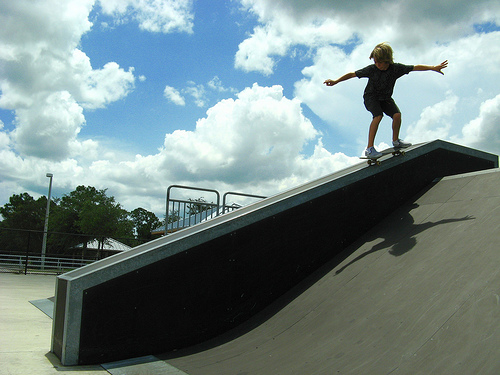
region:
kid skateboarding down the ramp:
[65, 30, 463, 336]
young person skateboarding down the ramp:
[35, 21, 457, 336]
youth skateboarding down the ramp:
[45, 12, 455, 328]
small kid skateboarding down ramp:
[20, 20, 465, 321]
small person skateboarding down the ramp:
[75, 30, 465, 325]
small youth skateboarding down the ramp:
[90, 25, 457, 325]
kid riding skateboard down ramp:
[41, 15, 468, 330]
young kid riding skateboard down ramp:
[57, 21, 459, 316]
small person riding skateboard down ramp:
[65, 20, 462, 295]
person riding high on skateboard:
[301, 8, 457, 206]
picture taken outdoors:
[34, 44, 489, 320]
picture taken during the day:
[44, 30, 461, 358]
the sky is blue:
[76, 37, 174, 131]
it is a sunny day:
[72, 60, 172, 187]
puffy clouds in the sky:
[69, 9, 314, 202]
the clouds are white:
[60, 55, 319, 168]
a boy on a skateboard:
[305, 20, 435, 209]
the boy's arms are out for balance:
[300, 45, 476, 96]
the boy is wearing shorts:
[326, 108, 415, 127]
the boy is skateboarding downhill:
[77, 142, 496, 292]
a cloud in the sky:
[13, 91, 87, 175]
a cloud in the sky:
[99, 59, 138, 102]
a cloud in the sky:
[98, 152, 140, 189]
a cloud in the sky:
[159, 122, 204, 182]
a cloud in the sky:
[1, 148, 28, 184]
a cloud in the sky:
[23, 15, 83, 70]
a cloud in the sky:
[237, 16, 281, 78]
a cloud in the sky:
[309, 59, 344, 130]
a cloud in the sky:
[235, 85, 305, 167]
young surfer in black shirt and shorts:
[325, 42, 448, 166]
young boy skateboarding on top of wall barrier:
[318, 42, 450, 164]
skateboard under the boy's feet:
[361, 138, 413, 165]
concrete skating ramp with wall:
[49, 138, 499, 373]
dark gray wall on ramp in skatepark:
[44, 138, 497, 373]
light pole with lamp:
[36, 165, 56, 270]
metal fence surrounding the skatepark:
[0, 252, 95, 276]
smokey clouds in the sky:
[6, 2, 312, 161]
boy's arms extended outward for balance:
[322, 37, 449, 87]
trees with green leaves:
[1, 184, 130, 266]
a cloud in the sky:
[21, 91, 82, 160]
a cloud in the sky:
[84, 151, 121, 193]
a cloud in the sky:
[73, 138, 110, 163]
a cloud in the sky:
[140, 87, 315, 174]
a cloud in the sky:
[166, 80, 187, 104]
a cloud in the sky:
[406, 89, 472, 140]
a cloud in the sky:
[463, 92, 498, 141]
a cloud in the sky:
[301, 139, 351, 170]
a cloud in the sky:
[1, 126, 8, 148]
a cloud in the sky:
[86, 2, 208, 45]